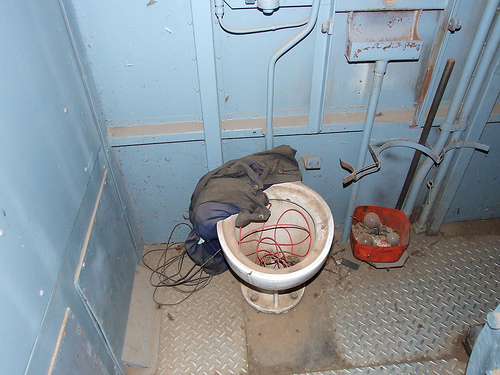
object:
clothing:
[183, 143, 303, 277]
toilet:
[217, 180, 335, 316]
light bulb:
[362, 212, 384, 228]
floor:
[114, 218, 500, 373]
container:
[349, 204, 411, 262]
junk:
[372, 237, 387, 248]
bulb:
[384, 227, 402, 248]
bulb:
[356, 231, 374, 247]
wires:
[238, 209, 311, 268]